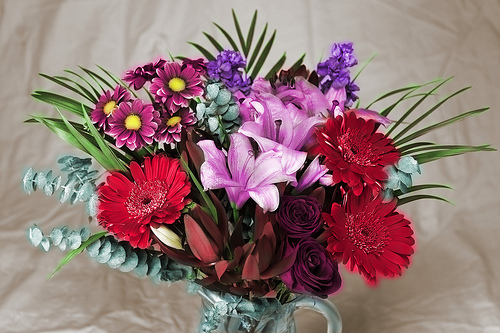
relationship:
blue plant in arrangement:
[29, 224, 186, 285] [21, 9, 498, 300]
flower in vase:
[97, 56, 420, 295] [194, 287, 348, 332]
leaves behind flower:
[23, 64, 142, 181] [97, 56, 420, 295]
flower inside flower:
[97, 56, 420, 295] [97, 154, 189, 249]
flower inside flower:
[97, 56, 420, 295] [195, 75, 391, 205]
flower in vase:
[97, 56, 420, 295] [186, 265, 354, 331]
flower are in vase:
[97, 56, 420, 295] [194, 287, 348, 332]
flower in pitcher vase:
[97, 56, 420, 295] [186, 281, 343, 331]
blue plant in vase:
[29, 224, 176, 290] [194, 291, 344, 331]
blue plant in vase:
[29, 224, 186, 285] [194, 291, 344, 331]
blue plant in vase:
[53, 152, 103, 190] [194, 291, 344, 331]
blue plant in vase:
[191, 82, 243, 146] [194, 291, 344, 331]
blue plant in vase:
[381, 157, 421, 199] [194, 291, 344, 331]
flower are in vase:
[97, 56, 420, 295] [154, 226, 254, 326]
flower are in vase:
[97, 56, 420, 295] [177, 275, 354, 332]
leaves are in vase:
[23, 64, 142, 181] [190, 283, 351, 332]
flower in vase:
[97, 56, 420, 295] [190, 283, 351, 332]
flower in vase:
[87, 148, 194, 254] [190, 283, 351, 332]